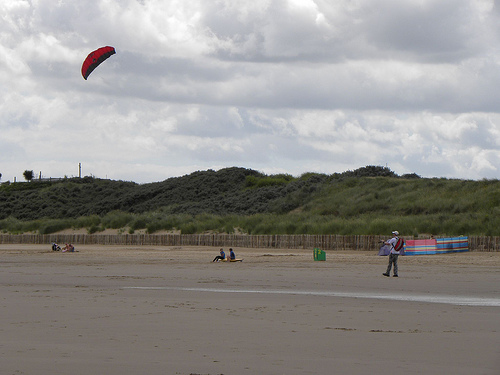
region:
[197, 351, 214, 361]
black mark is spotted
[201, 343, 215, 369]
black mark is spotted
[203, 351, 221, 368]
black mark is spotted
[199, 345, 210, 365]
black mark is spotted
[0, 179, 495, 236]
hill with lush greenery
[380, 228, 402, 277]
man with a backpack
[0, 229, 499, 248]
a long wooden fence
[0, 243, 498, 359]
a sandy beach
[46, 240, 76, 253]
two people on a beach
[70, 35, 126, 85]
kite in a cloudy sky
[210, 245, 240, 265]
two people on a blanket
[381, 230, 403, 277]
man wearing a baseball cap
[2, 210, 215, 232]
tall grass growing in sand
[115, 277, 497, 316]
a wet patch of sand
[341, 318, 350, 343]
balck mark is spotted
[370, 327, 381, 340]
balck mark is spotted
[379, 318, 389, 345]
balck mark is spotted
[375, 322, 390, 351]
balck mark is spotted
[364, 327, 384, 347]
balck mark is spotted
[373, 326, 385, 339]
balck mark is spotted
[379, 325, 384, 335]
balck mark is spotted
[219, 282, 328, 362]
the ground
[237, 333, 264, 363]
the ground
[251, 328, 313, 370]
the ground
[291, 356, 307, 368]
the ground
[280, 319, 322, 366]
the ground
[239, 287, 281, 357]
the ground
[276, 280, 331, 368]
the ground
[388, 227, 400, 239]
the head of a man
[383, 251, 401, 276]
a pair of gray pants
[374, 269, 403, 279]
a pair of black shoes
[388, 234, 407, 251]
a backpack on the man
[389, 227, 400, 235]
a gray hat on the man's head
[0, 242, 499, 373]
a brown sandy beach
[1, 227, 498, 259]
a small wooden fence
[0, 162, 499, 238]
a grassy green hill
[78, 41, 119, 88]
a kite in the sky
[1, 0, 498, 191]
a cloudy sky